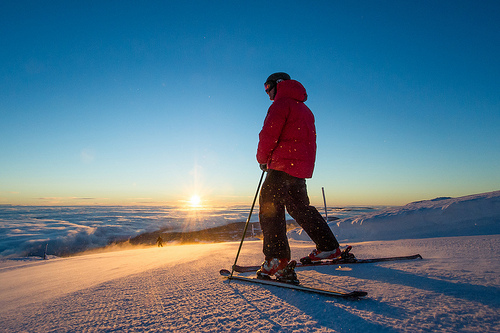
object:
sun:
[181, 193, 208, 210]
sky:
[0, 0, 499, 211]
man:
[255, 70, 358, 286]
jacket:
[256, 79, 318, 179]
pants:
[257, 168, 341, 260]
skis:
[228, 275, 368, 298]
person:
[155, 235, 164, 248]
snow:
[0, 235, 500, 333]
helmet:
[264, 71, 292, 100]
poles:
[229, 170, 266, 279]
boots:
[256, 257, 301, 285]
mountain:
[64, 189, 500, 333]